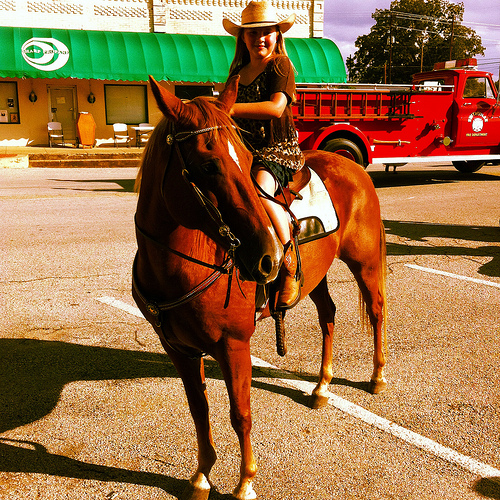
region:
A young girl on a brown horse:
[196, 1, 326, 267]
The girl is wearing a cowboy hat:
[218, 1, 295, 49]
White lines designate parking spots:
[351, 399, 480, 491]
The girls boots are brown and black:
[276, 227, 303, 317]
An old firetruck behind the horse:
[262, 69, 491, 162]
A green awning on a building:
[1, 22, 340, 83]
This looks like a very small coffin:
[68, 99, 98, 146]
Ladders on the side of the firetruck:
[286, 84, 421, 128]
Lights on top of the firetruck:
[422, 57, 482, 72]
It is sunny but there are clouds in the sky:
[322, 11, 491, 62]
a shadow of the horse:
[12, 327, 127, 484]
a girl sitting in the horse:
[187, 11, 348, 309]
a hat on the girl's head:
[218, 1, 298, 37]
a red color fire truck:
[302, 58, 494, 164]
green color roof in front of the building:
[9, 25, 348, 82]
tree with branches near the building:
[364, 0, 488, 72]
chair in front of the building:
[44, 118, 66, 143]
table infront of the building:
[131, 122, 153, 148]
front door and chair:
[45, 82, 90, 147]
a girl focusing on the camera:
[221, 0, 326, 201]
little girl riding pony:
[169, 4, 390, 464]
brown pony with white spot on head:
[145, 110, 455, 465]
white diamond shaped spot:
[222, 139, 272, 186]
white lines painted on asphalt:
[169, 322, 480, 467]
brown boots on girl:
[277, 249, 316, 316]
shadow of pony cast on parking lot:
[10, 310, 277, 496]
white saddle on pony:
[280, 186, 360, 245]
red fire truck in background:
[292, 85, 489, 173]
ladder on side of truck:
[254, 75, 434, 130]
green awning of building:
[2, 34, 287, 100]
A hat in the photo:
[215, 4, 296, 34]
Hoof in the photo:
[305, 384, 338, 416]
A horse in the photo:
[114, 86, 405, 495]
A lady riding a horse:
[210, 0, 340, 256]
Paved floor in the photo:
[423, 297, 490, 406]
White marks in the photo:
[397, 424, 488, 490]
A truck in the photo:
[296, 85, 473, 153]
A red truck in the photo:
[301, 66, 496, 158]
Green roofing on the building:
[45, 30, 170, 73]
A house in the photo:
[26, 82, 126, 144]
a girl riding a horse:
[128, 0, 388, 497]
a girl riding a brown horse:
[129, 1, 387, 498]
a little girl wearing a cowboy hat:
[196, 1, 318, 312]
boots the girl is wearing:
[276, 243, 304, 310]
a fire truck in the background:
[307, 56, 497, 171]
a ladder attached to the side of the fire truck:
[298, 86, 420, 121]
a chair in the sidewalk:
[46, 121, 64, 147]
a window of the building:
[103, 84, 148, 124]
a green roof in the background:
[0, 28, 349, 83]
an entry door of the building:
[47, 83, 82, 145]